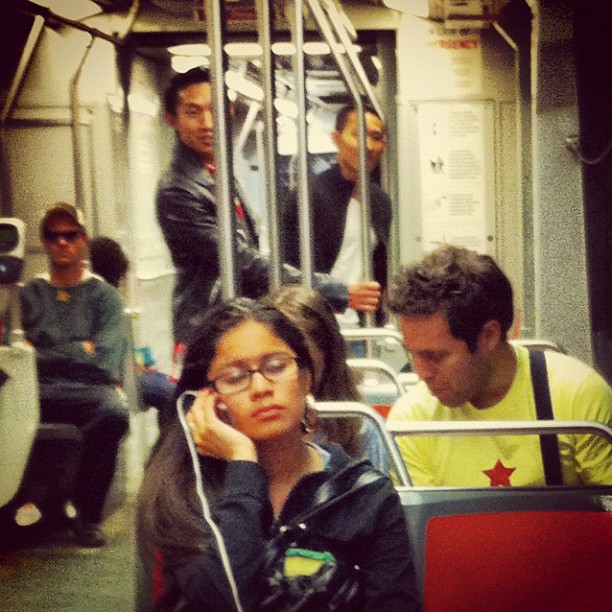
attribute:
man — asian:
[160, 68, 375, 392]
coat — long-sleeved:
[282, 166, 390, 298]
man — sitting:
[23, 204, 126, 544]